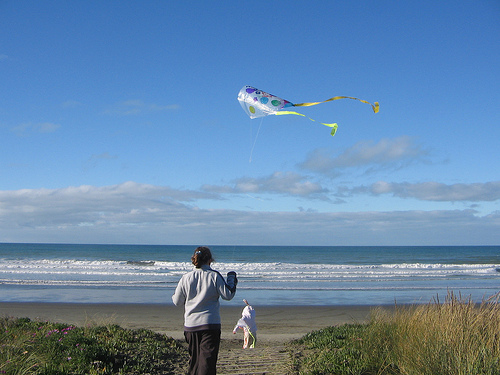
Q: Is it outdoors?
A: Yes, it is outdoors.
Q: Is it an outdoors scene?
A: Yes, it is outdoors.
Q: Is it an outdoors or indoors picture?
A: It is outdoors.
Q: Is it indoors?
A: No, it is outdoors.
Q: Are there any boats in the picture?
A: No, there are no boats.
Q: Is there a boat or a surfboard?
A: No, there are no boats or surfboards.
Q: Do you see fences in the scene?
A: No, there are no fences.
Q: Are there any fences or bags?
A: No, there are no fences or bags.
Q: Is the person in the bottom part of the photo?
A: Yes, the person is in the bottom of the image.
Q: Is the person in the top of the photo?
A: No, the person is in the bottom of the image.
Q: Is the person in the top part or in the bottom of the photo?
A: The person is in the bottom of the image.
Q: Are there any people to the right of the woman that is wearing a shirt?
A: Yes, there is a person to the right of the woman.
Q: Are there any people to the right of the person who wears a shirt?
A: Yes, there is a person to the right of the woman.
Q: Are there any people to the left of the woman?
A: No, the person is to the right of the woman.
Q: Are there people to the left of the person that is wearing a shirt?
A: No, the person is to the right of the woman.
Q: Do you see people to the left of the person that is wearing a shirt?
A: No, the person is to the right of the woman.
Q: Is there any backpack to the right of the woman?
A: No, there is a person to the right of the woman.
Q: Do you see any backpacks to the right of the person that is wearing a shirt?
A: No, there is a person to the right of the woman.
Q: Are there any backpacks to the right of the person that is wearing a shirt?
A: No, there is a person to the right of the woman.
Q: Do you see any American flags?
A: No, there are no American flags.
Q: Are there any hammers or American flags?
A: No, there are no American flags or hammers.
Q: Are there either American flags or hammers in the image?
A: No, there are no American flags or hammers.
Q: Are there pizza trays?
A: No, there are no pizza trays.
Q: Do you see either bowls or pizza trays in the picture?
A: No, there are no pizza trays or bowls.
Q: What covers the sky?
A: The clouds cover the sky.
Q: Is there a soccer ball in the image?
A: No, there are no soccer balls.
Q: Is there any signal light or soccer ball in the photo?
A: No, there are no soccer balls or traffic lights.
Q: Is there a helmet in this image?
A: No, there are no helmets.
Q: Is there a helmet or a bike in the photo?
A: No, there are no helmets or bikes.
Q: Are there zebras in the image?
A: No, there are no zebras.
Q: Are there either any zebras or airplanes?
A: No, there are no zebras or airplanes.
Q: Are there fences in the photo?
A: No, there are no fences.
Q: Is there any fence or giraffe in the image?
A: No, there are no fences or giraffes.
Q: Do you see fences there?
A: No, there are no fences.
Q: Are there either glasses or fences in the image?
A: No, there are no fences or glasses.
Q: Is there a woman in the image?
A: Yes, there is a woman.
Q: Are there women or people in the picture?
A: Yes, there is a woman.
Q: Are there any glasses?
A: No, there are no glasses.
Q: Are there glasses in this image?
A: No, there are no glasses.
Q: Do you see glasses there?
A: No, there are no glasses.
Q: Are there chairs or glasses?
A: No, there are no glasses or chairs.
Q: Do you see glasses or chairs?
A: No, there are no glasses or chairs.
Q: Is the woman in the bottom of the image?
A: Yes, the woman is in the bottom of the image.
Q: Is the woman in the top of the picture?
A: No, the woman is in the bottom of the image.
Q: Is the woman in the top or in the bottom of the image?
A: The woman is in the bottom of the image.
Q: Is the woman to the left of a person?
A: Yes, the woman is to the left of a person.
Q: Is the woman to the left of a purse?
A: No, the woman is to the left of a person.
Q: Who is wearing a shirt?
A: The woman is wearing a shirt.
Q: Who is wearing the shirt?
A: The woman is wearing a shirt.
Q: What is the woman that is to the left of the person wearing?
A: The woman is wearing a shirt.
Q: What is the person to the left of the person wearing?
A: The woman is wearing a shirt.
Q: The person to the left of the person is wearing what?
A: The woman is wearing a shirt.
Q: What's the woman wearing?
A: The woman is wearing a shirt.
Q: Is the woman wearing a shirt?
A: Yes, the woman is wearing a shirt.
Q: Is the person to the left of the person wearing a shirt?
A: Yes, the woman is wearing a shirt.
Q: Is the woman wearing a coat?
A: No, the woman is wearing a shirt.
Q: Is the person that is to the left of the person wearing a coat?
A: No, the woman is wearing a shirt.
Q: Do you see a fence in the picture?
A: No, there are no fences.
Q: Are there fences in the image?
A: No, there are no fences.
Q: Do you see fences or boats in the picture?
A: No, there are no fences or boats.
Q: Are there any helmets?
A: No, there are no helmets.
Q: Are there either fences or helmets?
A: No, there are no helmets or fences.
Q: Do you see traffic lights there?
A: No, there are no traffic lights.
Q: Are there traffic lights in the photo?
A: No, there are no traffic lights.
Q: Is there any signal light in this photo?
A: No, there are no traffic lights.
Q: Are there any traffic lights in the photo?
A: No, there are no traffic lights.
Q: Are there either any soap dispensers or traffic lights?
A: No, there are no traffic lights or soap dispensers.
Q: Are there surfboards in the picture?
A: No, there are no surfboards.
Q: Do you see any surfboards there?
A: No, there are no surfboards.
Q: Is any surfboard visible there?
A: No, there are no surfboards.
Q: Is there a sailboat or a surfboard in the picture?
A: No, there are no surfboards or sailboats.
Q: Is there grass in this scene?
A: Yes, there is grass.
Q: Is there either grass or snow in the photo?
A: Yes, there is grass.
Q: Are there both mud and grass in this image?
A: No, there is grass but no mud.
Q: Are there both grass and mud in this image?
A: No, there is grass but no mud.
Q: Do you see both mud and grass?
A: No, there is grass but no mud.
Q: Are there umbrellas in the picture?
A: No, there are no umbrellas.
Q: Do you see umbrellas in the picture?
A: No, there are no umbrellas.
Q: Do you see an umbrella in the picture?
A: No, there are no umbrellas.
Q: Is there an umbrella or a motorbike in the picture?
A: No, there are no umbrellas or motorcycles.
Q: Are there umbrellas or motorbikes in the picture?
A: No, there are no umbrellas or motorbikes.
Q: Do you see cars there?
A: No, there are no cars.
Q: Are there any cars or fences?
A: No, there are no cars or fences.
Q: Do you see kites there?
A: Yes, there is a kite.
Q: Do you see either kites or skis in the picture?
A: Yes, there is a kite.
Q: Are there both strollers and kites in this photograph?
A: No, there is a kite but no strollers.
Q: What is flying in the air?
A: The kite is flying in the air.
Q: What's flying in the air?
A: The kite is flying in the air.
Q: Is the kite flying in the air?
A: Yes, the kite is flying in the air.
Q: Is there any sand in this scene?
A: Yes, there is sand.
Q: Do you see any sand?
A: Yes, there is sand.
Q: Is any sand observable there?
A: Yes, there is sand.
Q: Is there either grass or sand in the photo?
A: Yes, there is sand.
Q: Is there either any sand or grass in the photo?
A: Yes, there is sand.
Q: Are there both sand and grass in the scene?
A: Yes, there are both sand and grass.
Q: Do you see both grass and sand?
A: Yes, there are both sand and grass.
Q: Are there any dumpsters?
A: No, there are no dumpsters.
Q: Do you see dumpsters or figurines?
A: No, there are no dumpsters or figurines.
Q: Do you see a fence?
A: No, there are no fences.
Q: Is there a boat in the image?
A: No, there are no boats.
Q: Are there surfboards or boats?
A: No, there are no boats or surfboards.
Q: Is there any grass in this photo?
A: Yes, there is grass.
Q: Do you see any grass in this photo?
A: Yes, there is grass.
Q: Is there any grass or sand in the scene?
A: Yes, there is grass.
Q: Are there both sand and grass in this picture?
A: Yes, there are both grass and sand.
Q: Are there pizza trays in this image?
A: No, there are no pizza trays.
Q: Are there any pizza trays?
A: No, there are no pizza trays.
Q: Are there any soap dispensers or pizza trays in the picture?
A: No, there are no pizza trays or soap dispensers.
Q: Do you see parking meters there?
A: No, there are no parking meters.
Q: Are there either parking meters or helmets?
A: No, there are no parking meters or helmets.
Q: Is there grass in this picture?
A: Yes, there is grass.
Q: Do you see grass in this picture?
A: Yes, there is grass.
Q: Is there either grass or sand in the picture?
A: Yes, there is grass.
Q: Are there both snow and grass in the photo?
A: No, there is grass but no snow.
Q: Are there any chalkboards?
A: No, there are no chalkboards.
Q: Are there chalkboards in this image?
A: No, there are no chalkboards.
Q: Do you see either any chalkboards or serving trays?
A: No, there are no chalkboards or serving trays.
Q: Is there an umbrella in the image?
A: No, there are no umbrellas.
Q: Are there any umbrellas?
A: No, there are no umbrellas.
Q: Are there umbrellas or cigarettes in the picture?
A: No, there are no umbrellas or cigarettes.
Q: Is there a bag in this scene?
A: No, there are no bags.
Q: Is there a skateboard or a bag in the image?
A: No, there are no bags or skateboards.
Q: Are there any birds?
A: No, there are no birds.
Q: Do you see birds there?
A: No, there are no birds.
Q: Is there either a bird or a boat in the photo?
A: No, there are no birds or boats.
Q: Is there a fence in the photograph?
A: No, there are no fences.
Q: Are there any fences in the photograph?
A: No, there are no fences.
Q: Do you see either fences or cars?
A: No, there are no fences or cars.